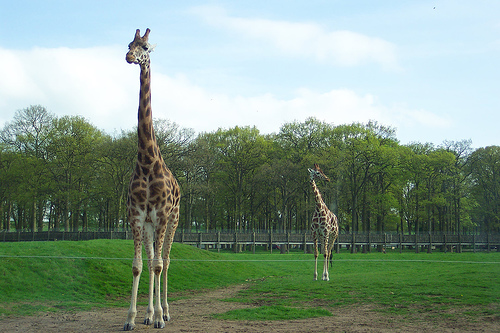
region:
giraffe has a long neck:
[291, 141, 355, 301]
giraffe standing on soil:
[95, 17, 218, 329]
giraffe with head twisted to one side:
[285, 150, 365, 285]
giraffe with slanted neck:
[295, 150, 335, 220]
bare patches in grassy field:
[190, 281, 445, 326]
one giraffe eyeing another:
[91, 35, 351, 325]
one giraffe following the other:
[100, 25, 350, 325]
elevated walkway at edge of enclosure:
[185, 217, 495, 275]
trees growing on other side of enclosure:
[187, 115, 484, 247]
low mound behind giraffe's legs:
[15, 205, 240, 312]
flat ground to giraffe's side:
[261, 156, 479, 292]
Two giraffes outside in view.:
[42, 17, 454, 311]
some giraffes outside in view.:
[69, 21, 427, 315]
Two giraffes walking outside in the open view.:
[55, 17, 425, 319]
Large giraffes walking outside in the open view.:
[49, 24, 418, 319]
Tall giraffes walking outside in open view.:
[57, 1, 426, 321]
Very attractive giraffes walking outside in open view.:
[75, 3, 439, 321]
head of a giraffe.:
[112, 16, 160, 77]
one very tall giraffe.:
[77, 13, 199, 326]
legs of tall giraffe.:
[108, 223, 188, 328]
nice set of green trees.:
[343, 149, 478, 239]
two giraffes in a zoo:
[105, 8, 360, 325]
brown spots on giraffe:
[137, 156, 161, 193]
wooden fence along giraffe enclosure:
[395, 230, 485, 252]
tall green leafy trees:
[228, 122, 275, 245]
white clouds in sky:
[177, 45, 312, 115]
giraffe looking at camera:
[116, 22, 197, 330]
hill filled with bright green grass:
[24, 231, 119, 299]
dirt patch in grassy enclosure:
[197, 271, 271, 327]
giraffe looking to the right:
[292, 136, 361, 289]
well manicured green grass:
[362, 245, 496, 289]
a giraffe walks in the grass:
[295, 155, 367, 283]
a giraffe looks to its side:
[275, 148, 373, 303]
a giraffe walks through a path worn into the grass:
[101, 20, 204, 330]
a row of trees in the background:
[55, 141, 480, 226]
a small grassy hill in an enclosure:
[0, 230, 235, 285]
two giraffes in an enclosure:
[58, 9, 419, 324]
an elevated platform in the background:
[165, 232, 496, 250]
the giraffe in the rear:
[290, 153, 365, 306]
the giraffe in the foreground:
[108, 23, 202, 331]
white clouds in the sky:
[157, 8, 462, 120]